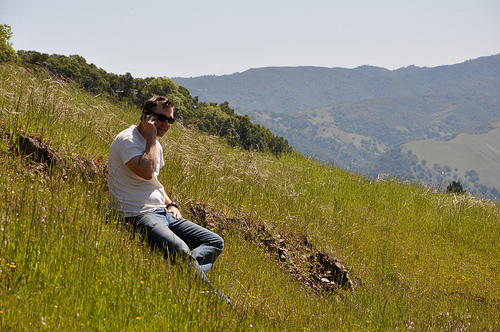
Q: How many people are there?
A: One.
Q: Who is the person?
A: A man.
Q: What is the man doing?
A: Talking.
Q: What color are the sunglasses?
A: Black.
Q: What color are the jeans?
A: Blue.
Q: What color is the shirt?
A: White.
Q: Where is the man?
A: The mountains.